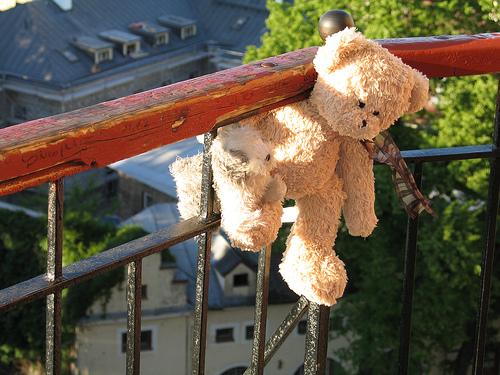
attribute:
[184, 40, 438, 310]
bear — hanging, stuck, white, brown, dressed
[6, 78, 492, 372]
railings — black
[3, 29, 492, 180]
wood — red, marked, chipping, discolored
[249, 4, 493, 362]
tree — green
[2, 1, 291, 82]
roof — gray